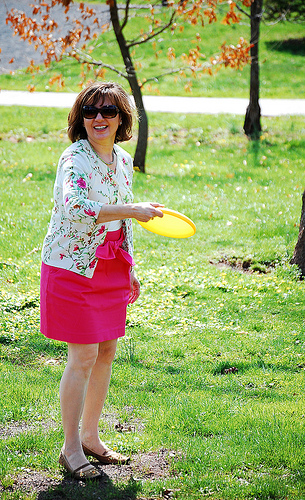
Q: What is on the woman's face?
A: Sunglasses.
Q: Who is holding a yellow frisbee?
A: Woman with brown hair.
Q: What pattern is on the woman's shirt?
A: Pink flowers with green leaves.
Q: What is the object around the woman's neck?
A: Green necklace.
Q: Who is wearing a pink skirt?
A: Woman throwing frisbee.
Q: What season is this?
A: Fall.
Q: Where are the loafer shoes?
A: In the dirt.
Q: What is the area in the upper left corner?
A: Lake.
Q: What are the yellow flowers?
A: Dandelions.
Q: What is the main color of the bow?
A: Pink.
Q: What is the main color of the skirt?
A: Pink.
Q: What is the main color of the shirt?
A: White.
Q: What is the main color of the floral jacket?
A: White.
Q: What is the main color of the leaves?
A: Brown.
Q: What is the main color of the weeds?
A: Green.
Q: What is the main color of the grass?
A: Green.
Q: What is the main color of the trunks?
A: Brown.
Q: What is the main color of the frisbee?
A: Yellow.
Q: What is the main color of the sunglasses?
A: Brown.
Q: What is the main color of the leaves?
A: Brown.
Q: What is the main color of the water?
A: Blue.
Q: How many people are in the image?
A: 1.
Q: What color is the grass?
A: Green.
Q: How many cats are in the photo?
A: 0.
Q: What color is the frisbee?
A: Yellow.